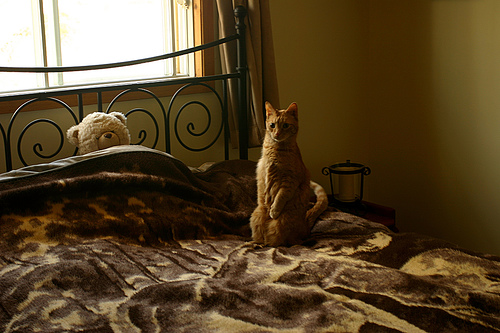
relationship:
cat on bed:
[249, 100, 327, 242] [4, 31, 498, 331]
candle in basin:
[339, 159, 355, 200] [320, 156, 374, 208]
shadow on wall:
[335, 3, 447, 246] [325, 34, 465, 123]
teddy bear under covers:
[66, 111, 130, 154] [4, 165, 499, 323]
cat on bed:
[249, 100, 327, 242] [0, 202, 498, 331]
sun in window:
[54, 10, 194, 81] [17, 16, 211, 84]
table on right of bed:
[302, 131, 446, 283] [4, 31, 498, 331]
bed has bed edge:
[4, 31, 498, 331] [0, 112, 250, 192]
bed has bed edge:
[0, 31, 497, 331] [313, 197, 498, 276]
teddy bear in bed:
[66, 108, 140, 155] [4, 31, 498, 331]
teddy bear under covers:
[66, 111, 130, 154] [3, 154, 498, 331]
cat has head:
[249, 100, 327, 242] [257, 96, 304, 149]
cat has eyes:
[249, 101, 328, 247] [263, 117, 288, 130]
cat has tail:
[249, 101, 328, 247] [300, 179, 325, 220]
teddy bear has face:
[66, 111, 130, 154] [94, 129, 123, 149]